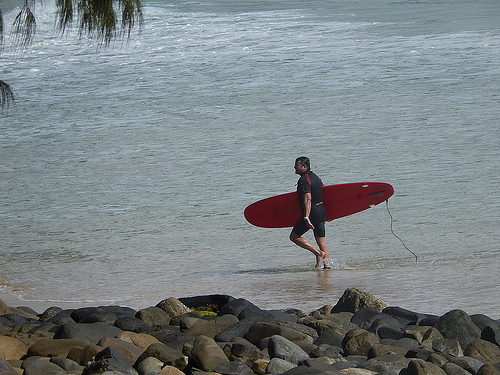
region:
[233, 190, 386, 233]
man holds red board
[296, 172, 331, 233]
man has black wetsuit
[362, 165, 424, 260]
black cable on board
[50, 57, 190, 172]
water is light grey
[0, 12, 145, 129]
green tree overhanging water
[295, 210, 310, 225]
man has white watch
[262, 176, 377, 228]
red and black board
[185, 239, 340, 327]
shallow water near shore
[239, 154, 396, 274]
surfer walking in shallow water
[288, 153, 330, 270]
one man wearing short black wetsuit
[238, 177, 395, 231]
one dark red surfboard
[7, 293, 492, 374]
section of large dark rocks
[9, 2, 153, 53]
bits of greenery hanging over ocean water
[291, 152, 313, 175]
man with short dark wet hair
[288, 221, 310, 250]
one bent male left knee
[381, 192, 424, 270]
one dark surfboard tether cord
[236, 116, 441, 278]
male surfer in the ocean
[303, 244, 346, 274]
two feet splashing in water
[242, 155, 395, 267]
man with a surf board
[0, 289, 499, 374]
rocks on the shore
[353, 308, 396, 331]
the rock is dark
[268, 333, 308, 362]
a gray colored rock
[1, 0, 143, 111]
fronds of a palm tree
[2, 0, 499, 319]
the water is blue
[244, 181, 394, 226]
the surf board is red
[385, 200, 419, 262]
leash on the surf board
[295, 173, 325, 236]
wet suit is black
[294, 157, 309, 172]
head of a man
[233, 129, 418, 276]
man walking with surf board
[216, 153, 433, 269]
man holding surf board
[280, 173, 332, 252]
wet suit on man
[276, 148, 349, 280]
man wearing a spring suit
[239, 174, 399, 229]
long red surf board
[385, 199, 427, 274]
black leash on board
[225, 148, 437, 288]
man walking through water with red board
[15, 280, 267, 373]
group of rocks on the beach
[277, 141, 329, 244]
Man in a black wet suit.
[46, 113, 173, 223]
Calm blue ocean water.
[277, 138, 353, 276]
Man walking in the ocean.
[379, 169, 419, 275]
Leash trailing on the surfboard.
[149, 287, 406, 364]
Many rocks among the shore.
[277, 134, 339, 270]
The man going surfing is named Marshall.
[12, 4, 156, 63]
Some leaves dripping from a tree.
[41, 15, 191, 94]
Little bit of foam from a wave.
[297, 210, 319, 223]
Marshall is wearing a white watch.